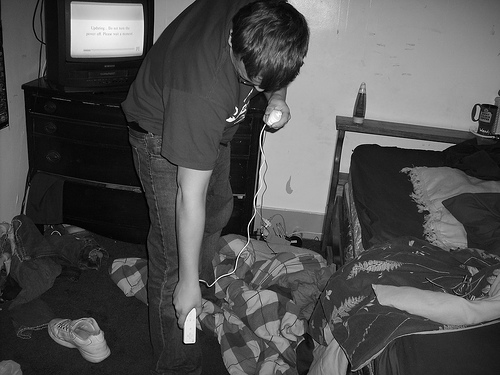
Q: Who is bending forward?
A: The man.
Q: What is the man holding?
A: A game controller.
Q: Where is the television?
A: Behind the man.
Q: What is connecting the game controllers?
A: A wire.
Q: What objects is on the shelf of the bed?
A: Mug and lamp.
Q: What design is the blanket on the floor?
A: Checkered.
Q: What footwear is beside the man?
A: Sneaker.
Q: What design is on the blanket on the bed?
A: Trees.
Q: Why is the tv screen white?
A: Tv is on.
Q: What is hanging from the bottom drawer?
A: Clothes.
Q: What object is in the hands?
A: Wii remote.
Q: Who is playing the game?
A: A man.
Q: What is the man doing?
A: Playing a game.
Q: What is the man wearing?
A: A shirt and jeans.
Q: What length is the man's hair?
A: Short.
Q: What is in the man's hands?
A: A game controller.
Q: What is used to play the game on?
A: The television.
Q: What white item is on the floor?
A: A shoe.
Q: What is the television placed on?
A: The dresser.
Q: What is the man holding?
A: A game controller.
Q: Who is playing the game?
A: A man.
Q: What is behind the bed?
A: The wall.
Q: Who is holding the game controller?
A: A man.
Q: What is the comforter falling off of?
A: The bed.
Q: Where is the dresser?
A: Under the TV.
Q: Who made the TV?
A: Sony.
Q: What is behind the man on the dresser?
A: A television.